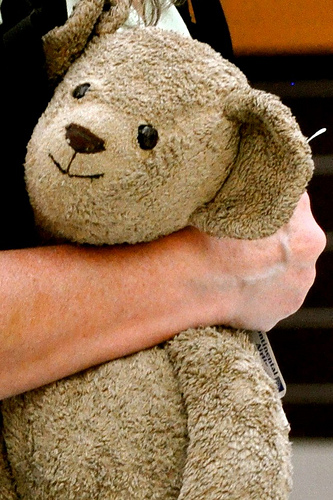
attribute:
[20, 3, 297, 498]
bear — tan, brown, furry, fuzzy, stuffed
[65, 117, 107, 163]
nose — brown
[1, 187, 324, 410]
arm — veiny, freckled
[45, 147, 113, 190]
mouth — black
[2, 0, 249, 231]
jacket — black